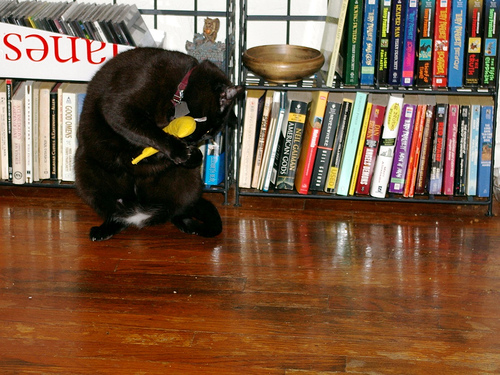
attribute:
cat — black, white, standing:
[72, 44, 244, 243]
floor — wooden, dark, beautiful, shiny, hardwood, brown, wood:
[0, 180, 499, 374]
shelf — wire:
[243, 68, 495, 97]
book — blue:
[360, 1, 377, 86]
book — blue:
[448, 1, 465, 88]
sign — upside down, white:
[1, 20, 137, 83]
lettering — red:
[3, 31, 121, 64]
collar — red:
[169, 62, 197, 111]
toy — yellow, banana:
[129, 115, 198, 165]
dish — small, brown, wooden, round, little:
[241, 42, 325, 85]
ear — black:
[222, 80, 247, 103]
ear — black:
[228, 106, 242, 128]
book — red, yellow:
[296, 89, 330, 193]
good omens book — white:
[60, 82, 85, 182]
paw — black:
[168, 137, 190, 166]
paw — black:
[183, 145, 203, 169]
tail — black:
[186, 195, 224, 236]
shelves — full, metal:
[1, 0, 499, 217]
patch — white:
[110, 201, 155, 230]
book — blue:
[477, 97, 494, 200]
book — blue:
[204, 131, 224, 187]